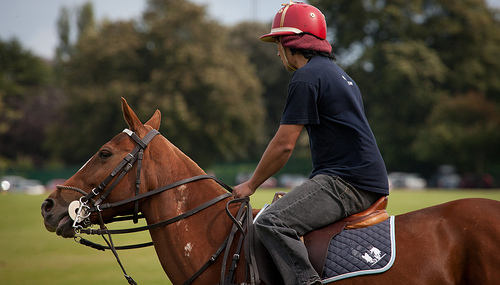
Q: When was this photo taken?
A: Daytime.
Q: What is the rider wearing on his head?
A: A helmet.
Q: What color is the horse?
A: Brown.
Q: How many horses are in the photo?
A: One.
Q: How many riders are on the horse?
A: One.